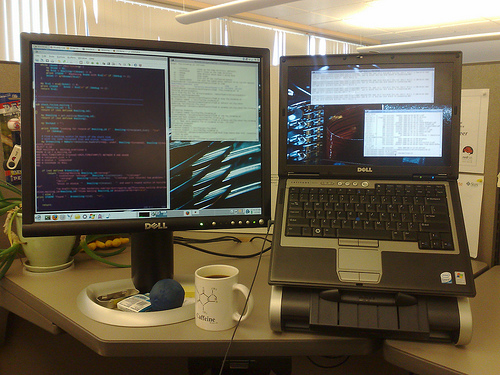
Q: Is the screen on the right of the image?
A: Yes, the screen is on the right of the image.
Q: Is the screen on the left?
A: No, the screen is on the right of the image.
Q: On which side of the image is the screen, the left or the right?
A: The screen is on the right of the image.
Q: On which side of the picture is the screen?
A: The screen is on the right of the image.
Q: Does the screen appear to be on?
A: Yes, the screen is on.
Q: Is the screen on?
A: Yes, the screen is on.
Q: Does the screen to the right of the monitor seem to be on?
A: Yes, the screen is on.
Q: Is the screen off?
A: No, the screen is on.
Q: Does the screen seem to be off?
A: No, the screen is on.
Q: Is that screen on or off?
A: The screen is on.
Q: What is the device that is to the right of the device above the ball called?
A: The device is a screen.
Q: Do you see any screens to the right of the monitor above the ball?
A: Yes, there is a screen to the right of the monitor.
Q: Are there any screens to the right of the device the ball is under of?
A: Yes, there is a screen to the right of the monitor.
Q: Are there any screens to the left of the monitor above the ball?
A: No, the screen is to the right of the monitor.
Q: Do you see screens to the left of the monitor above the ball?
A: No, the screen is to the right of the monitor.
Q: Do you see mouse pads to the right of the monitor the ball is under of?
A: No, there is a screen to the right of the monitor.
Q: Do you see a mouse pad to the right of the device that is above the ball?
A: No, there is a screen to the right of the monitor.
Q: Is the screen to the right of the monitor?
A: Yes, the screen is to the right of the monitor.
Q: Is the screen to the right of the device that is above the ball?
A: Yes, the screen is to the right of the monitor.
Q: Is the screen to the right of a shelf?
A: No, the screen is to the right of the monitor.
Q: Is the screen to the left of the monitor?
A: No, the screen is to the right of the monitor.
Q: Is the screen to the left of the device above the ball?
A: No, the screen is to the right of the monitor.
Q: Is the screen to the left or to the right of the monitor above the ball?
A: The screen is to the right of the monitor.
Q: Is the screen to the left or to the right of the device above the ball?
A: The screen is to the right of the monitor.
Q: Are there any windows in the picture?
A: Yes, there is a window.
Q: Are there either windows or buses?
A: Yes, there is a window.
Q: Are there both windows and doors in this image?
A: No, there is a window but no doors.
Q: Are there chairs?
A: No, there are no chairs.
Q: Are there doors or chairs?
A: No, there are no chairs or doors.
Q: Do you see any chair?
A: No, there are no chairs.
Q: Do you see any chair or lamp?
A: No, there are no chairs or lamps.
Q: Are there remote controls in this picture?
A: No, there are no remote controls.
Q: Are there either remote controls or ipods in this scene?
A: No, there are no remote controls or ipods.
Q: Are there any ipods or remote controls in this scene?
A: No, there are no remote controls or ipods.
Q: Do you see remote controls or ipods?
A: No, there are no remote controls or ipods.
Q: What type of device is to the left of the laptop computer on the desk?
A: The device is a monitor.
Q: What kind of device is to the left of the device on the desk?
A: The device is a monitor.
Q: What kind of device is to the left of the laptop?
A: The device is a monitor.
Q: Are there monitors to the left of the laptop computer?
A: Yes, there is a monitor to the left of the laptop computer.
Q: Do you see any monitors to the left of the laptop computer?
A: Yes, there is a monitor to the left of the laptop computer.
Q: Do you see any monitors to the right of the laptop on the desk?
A: No, the monitor is to the left of the laptop.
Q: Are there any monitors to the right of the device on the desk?
A: No, the monitor is to the left of the laptop.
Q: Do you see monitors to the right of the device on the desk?
A: No, the monitor is to the left of the laptop.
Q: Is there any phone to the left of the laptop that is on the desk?
A: No, there is a monitor to the left of the laptop.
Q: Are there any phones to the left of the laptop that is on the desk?
A: No, there is a monitor to the left of the laptop.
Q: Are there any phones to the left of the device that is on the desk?
A: No, there is a monitor to the left of the laptop.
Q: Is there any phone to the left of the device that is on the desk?
A: No, there is a monitor to the left of the laptop.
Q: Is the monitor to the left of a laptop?
A: Yes, the monitor is to the left of a laptop.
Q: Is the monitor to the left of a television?
A: No, the monitor is to the left of a laptop.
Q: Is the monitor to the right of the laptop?
A: No, the monitor is to the left of the laptop.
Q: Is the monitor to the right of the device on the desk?
A: No, the monitor is to the left of the laptop.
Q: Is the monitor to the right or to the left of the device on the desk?
A: The monitor is to the left of the laptop.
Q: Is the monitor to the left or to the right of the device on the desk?
A: The monitor is to the left of the laptop.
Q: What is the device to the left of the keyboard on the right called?
A: The device is a monitor.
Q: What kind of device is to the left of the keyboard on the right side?
A: The device is a monitor.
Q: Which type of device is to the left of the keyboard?
A: The device is a monitor.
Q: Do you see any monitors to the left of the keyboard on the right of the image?
A: Yes, there is a monitor to the left of the keyboard.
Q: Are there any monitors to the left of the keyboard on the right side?
A: Yes, there is a monitor to the left of the keyboard.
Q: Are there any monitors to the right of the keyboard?
A: No, the monitor is to the left of the keyboard.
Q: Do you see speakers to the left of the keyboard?
A: No, there is a monitor to the left of the keyboard.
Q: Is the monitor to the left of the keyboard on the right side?
A: Yes, the monitor is to the left of the keyboard.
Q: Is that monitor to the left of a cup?
A: No, the monitor is to the left of the keyboard.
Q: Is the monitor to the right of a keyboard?
A: No, the monitor is to the left of a keyboard.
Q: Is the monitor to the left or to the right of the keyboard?
A: The monitor is to the left of the keyboard.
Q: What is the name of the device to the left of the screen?
A: The device is a monitor.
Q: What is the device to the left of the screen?
A: The device is a monitor.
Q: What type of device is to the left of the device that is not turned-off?
A: The device is a monitor.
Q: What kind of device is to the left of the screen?
A: The device is a monitor.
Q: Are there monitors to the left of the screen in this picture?
A: Yes, there is a monitor to the left of the screen.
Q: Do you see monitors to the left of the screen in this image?
A: Yes, there is a monitor to the left of the screen.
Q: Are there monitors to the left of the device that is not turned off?
A: Yes, there is a monitor to the left of the screen.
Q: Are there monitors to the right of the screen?
A: No, the monitor is to the left of the screen.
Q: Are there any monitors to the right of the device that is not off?
A: No, the monitor is to the left of the screen.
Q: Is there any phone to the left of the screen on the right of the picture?
A: No, there is a monitor to the left of the screen.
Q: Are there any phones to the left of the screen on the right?
A: No, there is a monitor to the left of the screen.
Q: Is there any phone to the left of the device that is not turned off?
A: No, there is a monitor to the left of the screen.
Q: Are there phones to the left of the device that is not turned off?
A: No, there is a monitor to the left of the screen.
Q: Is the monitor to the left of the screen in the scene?
A: Yes, the monitor is to the left of the screen.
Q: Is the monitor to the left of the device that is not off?
A: Yes, the monitor is to the left of the screen.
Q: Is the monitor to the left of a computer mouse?
A: No, the monitor is to the left of the screen.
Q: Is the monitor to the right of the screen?
A: No, the monitor is to the left of the screen.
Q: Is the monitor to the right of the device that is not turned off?
A: No, the monitor is to the left of the screen.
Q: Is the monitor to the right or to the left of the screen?
A: The monitor is to the left of the screen.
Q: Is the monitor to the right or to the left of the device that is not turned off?
A: The monitor is to the left of the screen.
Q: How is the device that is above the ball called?
A: The device is a monitor.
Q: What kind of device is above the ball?
A: The device is a monitor.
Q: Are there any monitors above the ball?
A: Yes, there is a monitor above the ball.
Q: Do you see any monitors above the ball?
A: Yes, there is a monitor above the ball.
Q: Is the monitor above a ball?
A: Yes, the monitor is above a ball.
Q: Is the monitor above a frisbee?
A: No, the monitor is above a ball.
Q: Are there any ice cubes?
A: No, there are no ice cubes.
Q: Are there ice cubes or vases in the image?
A: No, there are no ice cubes or vases.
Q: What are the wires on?
A: The wires are on the desk.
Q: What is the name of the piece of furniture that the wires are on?
A: The piece of furniture is a desk.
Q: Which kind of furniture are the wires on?
A: The wires are on the desk.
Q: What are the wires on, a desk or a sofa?
A: The wires are on a desk.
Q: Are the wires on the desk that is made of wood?
A: Yes, the wires are on the desk.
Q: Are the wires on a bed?
A: No, the wires are on the desk.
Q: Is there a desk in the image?
A: Yes, there is a desk.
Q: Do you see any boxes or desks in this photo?
A: Yes, there is a desk.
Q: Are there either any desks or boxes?
A: Yes, there is a desk.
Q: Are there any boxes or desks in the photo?
A: Yes, there is a desk.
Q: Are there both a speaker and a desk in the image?
A: No, there is a desk but no speakers.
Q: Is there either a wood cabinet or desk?
A: Yes, there is a wood desk.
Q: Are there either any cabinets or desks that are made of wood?
A: Yes, the desk is made of wood.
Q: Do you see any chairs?
A: No, there are no chairs.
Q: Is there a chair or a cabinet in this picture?
A: No, there are no chairs or cabinets.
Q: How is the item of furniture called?
A: The piece of furniture is a desk.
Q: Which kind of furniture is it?
A: The piece of furniture is a desk.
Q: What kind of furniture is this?
A: This is a desk.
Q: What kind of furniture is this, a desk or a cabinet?
A: This is a desk.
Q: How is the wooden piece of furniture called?
A: The piece of furniture is a desk.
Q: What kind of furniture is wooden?
A: The furniture is a desk.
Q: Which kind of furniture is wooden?
A: The furniture is a desk.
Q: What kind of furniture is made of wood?
A: The furniture is a desk.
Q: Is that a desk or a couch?
A: That is a desk.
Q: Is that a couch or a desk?
A: That is a desk.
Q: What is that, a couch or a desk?
A: That is a desk.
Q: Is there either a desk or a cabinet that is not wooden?
A: No, there is a desk but it is wooden.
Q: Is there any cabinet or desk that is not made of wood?
A: No, there is a desk but it is made of wood.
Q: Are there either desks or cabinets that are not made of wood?
A: No, there is a desk but it is made of wood.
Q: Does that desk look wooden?
A: Yes, the desk is wooden.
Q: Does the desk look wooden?
A: Yes, the desk is wooden.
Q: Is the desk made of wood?
A: Yes, the desk is made of wood.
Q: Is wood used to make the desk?
A: Yes, the desk is made of wood.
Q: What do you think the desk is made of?
A: The desk is made of wood.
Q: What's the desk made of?
A: The desk is made of wood.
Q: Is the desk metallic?
A: No, the desk is wooden.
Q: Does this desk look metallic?
A: No, the desk is wooden.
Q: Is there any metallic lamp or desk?
A: No, there is a desk but it is wooden.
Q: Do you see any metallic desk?
A: No, there is a desk but it is wooden.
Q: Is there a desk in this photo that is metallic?
A: No, there is a desk but it is wooden.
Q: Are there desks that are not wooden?
A: No, there is a desk but it is wooden.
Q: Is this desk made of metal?
A: No, the desk is made of wood.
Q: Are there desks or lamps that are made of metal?
A: No, there is a desk but it is made of wood.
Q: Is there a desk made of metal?
A: No, there is a desk but it is made of wood.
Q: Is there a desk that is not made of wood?
A: No, there is a desk but it is made of wood.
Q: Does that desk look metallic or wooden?
A: The desk is wooden.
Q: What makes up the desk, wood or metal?
A: The desk is made of wood.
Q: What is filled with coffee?
A: The coffee cup is filled with coffee.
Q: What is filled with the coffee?
A: The coffee cup is filled with coffee.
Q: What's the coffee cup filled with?
A: The coffee cup is filled with coffee.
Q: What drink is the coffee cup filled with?
A: The coffee cup is filled with coffee.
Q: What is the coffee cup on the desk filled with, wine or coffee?
A: The coffee cup is filled with coffee.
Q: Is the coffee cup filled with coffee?
A: Yes, the coffee cup is filled with coffee.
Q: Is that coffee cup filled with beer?
A: No, the coffee cup is filled with coffee.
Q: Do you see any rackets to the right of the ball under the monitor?
A: No, there is a coffee cup to the right of the ball.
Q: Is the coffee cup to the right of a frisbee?
A: No, the coffee cup is to the right of a ball.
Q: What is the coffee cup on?
A: The coffee cup is on the desk.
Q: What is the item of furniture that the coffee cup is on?
A: The piece of furniture is a desk.